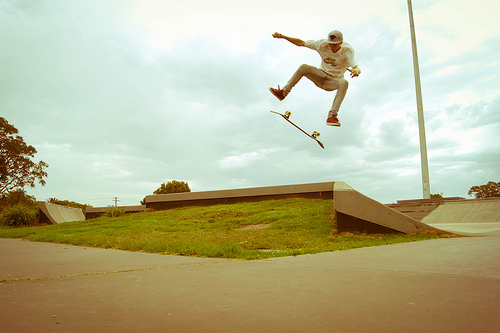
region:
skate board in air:
[273, 110, 328, 152]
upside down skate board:
[273, 108, 326, 149]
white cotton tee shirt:
[311, 40, 356, 77]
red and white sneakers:
[273, 85, 341, 127]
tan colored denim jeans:
[281, 61, 353, 111]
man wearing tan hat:
[265, 29, 364, 127]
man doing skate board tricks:
[272, 25, 359, 128]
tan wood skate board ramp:
[144, 179, 499, 242]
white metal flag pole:
[406, 3, 433, 203]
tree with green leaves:
[1, 115, 48, 210]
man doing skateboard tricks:
[266, 25, 358, 131]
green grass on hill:
[6, 199, 375, 255]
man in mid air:
[111, 8, 448, 266]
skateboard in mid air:
[258, 113, 326, 160]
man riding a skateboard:
[242, 23, 363, 158]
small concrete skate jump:
[310, 182, 425, 253]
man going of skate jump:
[215, 23, 462, 290]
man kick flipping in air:
[227, 25, 377, 162]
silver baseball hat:
[318, 21, 353, 56]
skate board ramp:
[331, 191, 496, 246]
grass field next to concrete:
[4, 181, 344, 319]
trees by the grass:
[0, 111, 60, 231]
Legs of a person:
[262, 66, 350, 128]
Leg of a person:
[323, 73, 352, 137]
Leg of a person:
[262, 60, 322, 100]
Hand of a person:
[342, 47, 365, 77]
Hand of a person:
[261, 20, 316, 56]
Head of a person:
[324, 24, 348, 53]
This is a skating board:
[254, 97, 334, 160]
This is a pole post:
[400, 0, 451, 220]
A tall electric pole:
[397, 0, 444, 210]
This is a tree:
[1, 111, 51, 223]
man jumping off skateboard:
[262, 17, 365, 151]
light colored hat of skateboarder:
[324, 26, 344, 46]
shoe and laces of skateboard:
[263, 83, 342, 131]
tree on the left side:
[0, 109, 49, 214]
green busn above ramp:
[144, 178, 196, 197]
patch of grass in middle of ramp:
[24, 208, 334, 252]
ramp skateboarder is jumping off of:
[319, 178, 491, 245]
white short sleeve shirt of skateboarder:
[302, 38, 358, 77]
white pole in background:
[398, 3, 437, 200]